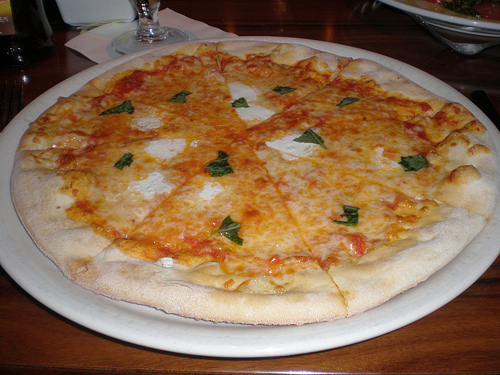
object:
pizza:
[6, 35, 494, 330]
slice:
[244, 132, 484, 318]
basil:
[237, 129, 493, 222]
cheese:
[98, 66, 425, 258]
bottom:
[111, 29, 191, 58]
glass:
[108, 1, 197, 55]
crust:
[17, 31, 493, 335]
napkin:
[63, 5, 242, 66]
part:
[15, 88, 28, 109]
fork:
[2, 78, 30, 129]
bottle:
[3, 2, 59, 77]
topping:
[8, 36, 500, 326]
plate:
[2, 35, 499, 365]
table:
[6, 6, 496, 373]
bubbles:
[429, 159, 489, 197]